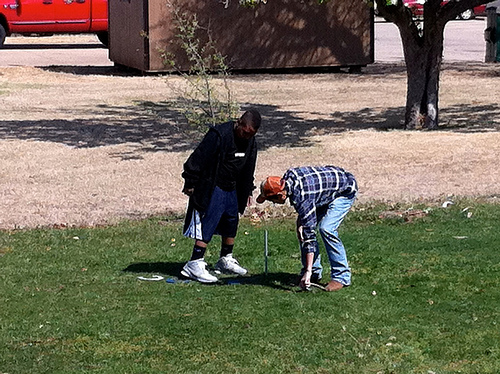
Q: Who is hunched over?
A: A man in a hat.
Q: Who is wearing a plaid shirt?
A: The man in a hat.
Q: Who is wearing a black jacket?
A: The man on the left.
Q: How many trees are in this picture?
A: Two.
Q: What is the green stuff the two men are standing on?
A: Grass.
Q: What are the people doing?
A: Bending down.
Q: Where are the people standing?
A: In the grass.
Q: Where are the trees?
A: In the back.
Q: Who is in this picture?
A: Two men.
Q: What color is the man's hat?
A: Red.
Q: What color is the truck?
A: Red truck.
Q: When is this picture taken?
A: Daylight hours.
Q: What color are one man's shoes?
A: White.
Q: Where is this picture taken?
A: On the grass.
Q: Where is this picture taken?
A: While playing golf.